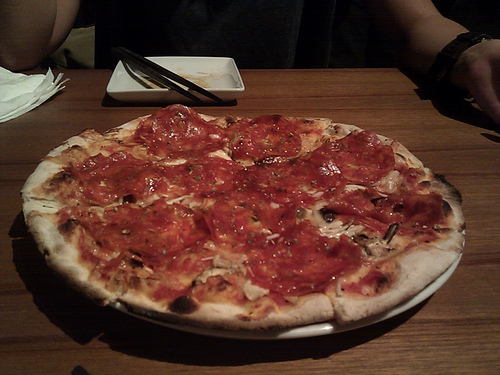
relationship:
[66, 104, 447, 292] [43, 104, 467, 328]
pepperoni on baked pizza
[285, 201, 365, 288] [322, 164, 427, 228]
topping on pizza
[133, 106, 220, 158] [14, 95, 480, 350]
pepperoni on plate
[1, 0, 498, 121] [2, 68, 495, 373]
person sitting at table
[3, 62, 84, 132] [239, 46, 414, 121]
paper towel on table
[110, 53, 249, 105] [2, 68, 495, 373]
bowl on table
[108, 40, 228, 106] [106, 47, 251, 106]
chopsticks on bowl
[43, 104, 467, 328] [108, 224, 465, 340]
baked pizza on plate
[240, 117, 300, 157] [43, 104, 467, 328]
pepperoni on baked pizza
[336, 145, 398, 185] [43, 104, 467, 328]
pepperoni on baked pizza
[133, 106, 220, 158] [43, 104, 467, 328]
pepperoni on baked pizza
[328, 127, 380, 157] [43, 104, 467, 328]
pepperoni on baked pizza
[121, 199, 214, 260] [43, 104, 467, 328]
pepperoni on baked pizza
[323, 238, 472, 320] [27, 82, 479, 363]
crust on pizza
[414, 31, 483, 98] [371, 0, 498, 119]
watch on person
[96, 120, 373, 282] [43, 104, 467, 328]
cheese on baked pizza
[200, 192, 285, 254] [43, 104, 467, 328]
topping on baked pizza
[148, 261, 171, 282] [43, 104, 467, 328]
topping on baked pizza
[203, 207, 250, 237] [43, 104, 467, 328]
topping on baked pizza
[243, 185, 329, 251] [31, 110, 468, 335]
topping on pizza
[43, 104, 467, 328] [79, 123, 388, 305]
baked pizza on pizza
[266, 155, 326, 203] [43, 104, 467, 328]
topping on baked pizza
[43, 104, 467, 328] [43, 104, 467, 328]
baked pizza on baked pizza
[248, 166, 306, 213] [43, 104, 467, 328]
topping on baked pizza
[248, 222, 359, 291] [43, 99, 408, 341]
pepperoni on baked pizza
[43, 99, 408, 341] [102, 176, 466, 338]
baked pizza on plate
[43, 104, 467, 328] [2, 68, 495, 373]
baked pizza on table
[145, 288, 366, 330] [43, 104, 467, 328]
crust on baked pizza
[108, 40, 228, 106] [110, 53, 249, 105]
chopsticks on bowl